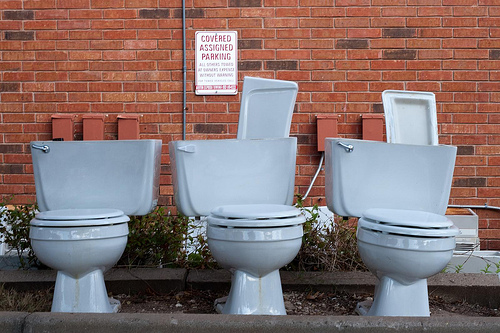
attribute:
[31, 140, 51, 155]
handle — silver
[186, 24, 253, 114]
sign — white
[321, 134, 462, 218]
tank — white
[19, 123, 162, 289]
toilet — white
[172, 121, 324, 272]
toilet — white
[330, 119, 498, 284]
toilet — white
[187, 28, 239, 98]
sign — white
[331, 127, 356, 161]
handle — silver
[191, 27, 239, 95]
sign — corner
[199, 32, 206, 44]
letters — red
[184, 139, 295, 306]
toilet — reflection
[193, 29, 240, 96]
sign — white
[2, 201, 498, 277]
weeds — green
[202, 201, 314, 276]
toilet — cover, closed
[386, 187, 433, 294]
bowl — White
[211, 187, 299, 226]
seat cover — white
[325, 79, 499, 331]
toilet — white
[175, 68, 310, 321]
toilet — white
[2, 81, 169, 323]
toilet — white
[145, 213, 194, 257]
plants — green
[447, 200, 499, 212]
pipe — metal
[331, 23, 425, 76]
bricks — dark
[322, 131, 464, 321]
toilet — white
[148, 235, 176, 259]
leaves — dry, brown